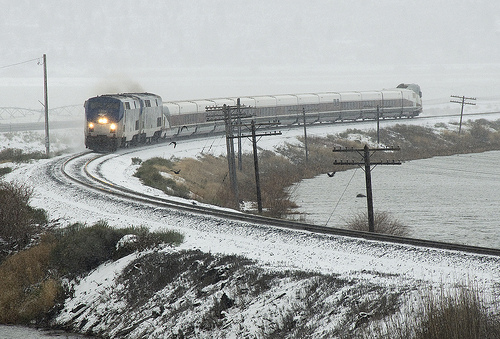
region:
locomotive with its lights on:
[81, 90, 162, 148]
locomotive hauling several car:
[80, 80, 419, 150]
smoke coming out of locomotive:
[86, 74, 162, 104]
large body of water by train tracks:
[271, 140, 497, 254]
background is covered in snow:
[0, 1, 497, 76]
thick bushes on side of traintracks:
[2, 220, 102, 322]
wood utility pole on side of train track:
[40, 50, 51, 157]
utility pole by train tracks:
[334, 138, 401, 233]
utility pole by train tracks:
[230, 119, 284, 215]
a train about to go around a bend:
[17, 28, 497, 293]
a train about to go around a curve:
[0, 13, 492, 305]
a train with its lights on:
[10, 20, 487, 330]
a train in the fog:
[19, 39, 497, 289]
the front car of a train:
[77, 85, 169, 161]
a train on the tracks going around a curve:
[8, 14, 498, 336]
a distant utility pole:
[20, 31, 71, 179]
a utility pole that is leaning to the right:
[441, 79, 488, 184]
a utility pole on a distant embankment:
[435, 70, 495, 190]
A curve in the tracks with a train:
[19, 11, 489, 324]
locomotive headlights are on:
[84, 96, 121, 151]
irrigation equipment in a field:
[4, 93, 89, 128]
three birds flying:
[164, 115, 191, 181]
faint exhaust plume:
[75, 49, 150, 98]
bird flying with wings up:
[321, 165, 339, 180]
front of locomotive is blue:
[82, 95, 123, 131]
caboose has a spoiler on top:
[395, 80, 427, 119]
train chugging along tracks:
[80, 74, 431, 154]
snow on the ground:
[185, 225, 435, 300]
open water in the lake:
[414, 175, 495, 230]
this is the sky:
[249, 13, 333, 37]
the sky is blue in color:
[251, 25, 314, 55]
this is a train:
[78, 92, 192, 147]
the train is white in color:
[118, 104, 158, 136]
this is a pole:
[38, 39, 62, 158]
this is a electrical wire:
[6, 50, 34, 81]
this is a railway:
[58, 138, 103, 223]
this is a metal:
[118, 187, 145, 199]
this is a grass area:
[68, 224, 108, 261]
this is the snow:
[233, 237, 273, 262]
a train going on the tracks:
[81, 76, 437, 145]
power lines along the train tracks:
[207, 98, 400, 229]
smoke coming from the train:
[100, 79, 172, 123]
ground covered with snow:
[305, 173, 477, 247]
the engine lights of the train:
[81, 92, 134, 162]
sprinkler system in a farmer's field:
[0, 100, 92, 131]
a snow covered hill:
[97, 240, 311, 335]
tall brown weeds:
[392, 282, 491, 337]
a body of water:
[17, 296, 124, 336]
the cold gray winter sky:
[19, 30, 488, 84]